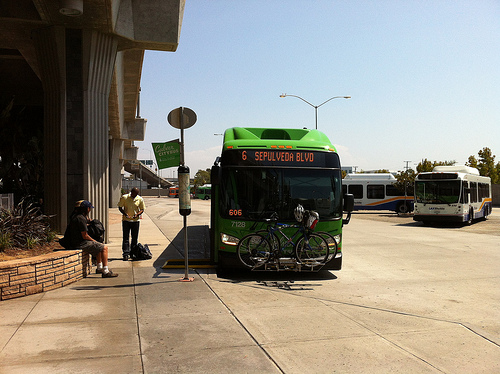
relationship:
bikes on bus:
[218, 163, 342, 291] [144, 100, 399, 307]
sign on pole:
[149, 135, 186, 172] [171, 129, 202, 280]